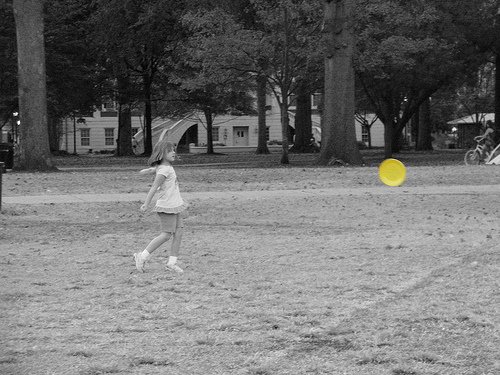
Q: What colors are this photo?
A: Black, white, yellow.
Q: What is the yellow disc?
A: Frisbee.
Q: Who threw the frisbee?
A: The girl.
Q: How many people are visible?
A: 2.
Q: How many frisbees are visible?
A: 1.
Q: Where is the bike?
A: Right side near the top.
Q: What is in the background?
A: Building.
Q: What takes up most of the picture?
A: Ground.